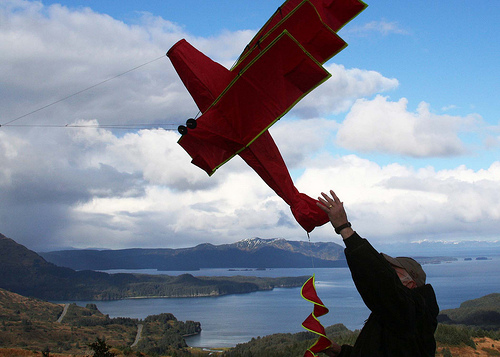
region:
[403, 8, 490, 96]
The sky is clear and blue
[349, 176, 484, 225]
The clouds are white and fluffy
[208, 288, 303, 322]
The lake water is calm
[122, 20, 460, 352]
The person has a kite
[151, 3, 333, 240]
The kite is the color red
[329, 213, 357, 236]
The man is wearing a watch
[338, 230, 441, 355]
The man is wearing a black jacket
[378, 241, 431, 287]
The man is wearing a hat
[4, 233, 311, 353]
The mountains are majestic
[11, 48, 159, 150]
The string to the kite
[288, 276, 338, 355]
tail of a kite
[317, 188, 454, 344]
man flying a kite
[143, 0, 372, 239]
red kite shaped like a plane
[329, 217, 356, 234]
watch on man's wrist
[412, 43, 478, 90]
blue sky in the distance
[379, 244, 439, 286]
baseball cap on a man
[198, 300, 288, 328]
water of an ocean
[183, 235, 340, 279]
land behind the water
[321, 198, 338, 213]
ring on man's left hand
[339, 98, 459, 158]
white cloud in the sky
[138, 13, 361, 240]
the kite is red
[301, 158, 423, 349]
man holding out the kite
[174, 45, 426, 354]
man holding out the kite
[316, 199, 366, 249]
the watch is black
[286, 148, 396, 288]
the watch is black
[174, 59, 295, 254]
This is an airplane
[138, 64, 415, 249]
This is a kite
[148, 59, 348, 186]
The plane is red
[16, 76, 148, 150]
This is small string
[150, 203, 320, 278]
These are large mountains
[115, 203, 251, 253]
These are some clouds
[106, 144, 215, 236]
The clouds are white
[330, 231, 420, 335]
This is a man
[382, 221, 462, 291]
This is a hat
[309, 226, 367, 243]
This is a bracelet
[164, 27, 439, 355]
man releasing red kite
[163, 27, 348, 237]
red kite is airplane-shaped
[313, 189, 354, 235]
left hand with wristwatch and wedding band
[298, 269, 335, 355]
red and yellow tail of kite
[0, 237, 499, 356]
two peninsulas jutting into large lake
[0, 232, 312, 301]
wooded peninsula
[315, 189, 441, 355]
man wearing dark jacket and ball cap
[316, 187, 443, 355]
man with outstretched left arm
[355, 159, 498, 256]
snow-covered mountains under clouds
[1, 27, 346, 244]
red kite and kite strings